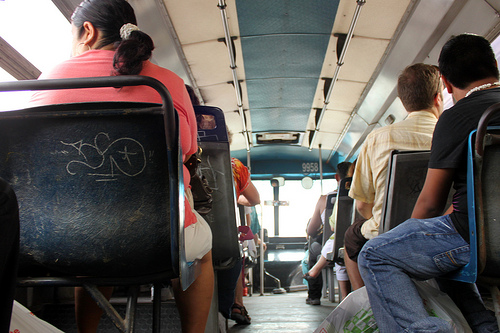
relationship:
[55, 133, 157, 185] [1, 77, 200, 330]
graffiti on seat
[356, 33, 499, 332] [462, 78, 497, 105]
bus rider wearing necklace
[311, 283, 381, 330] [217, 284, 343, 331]
shopping bag on floor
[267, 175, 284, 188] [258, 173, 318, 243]
mirror over windshield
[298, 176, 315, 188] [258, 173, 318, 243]
mirror over windshield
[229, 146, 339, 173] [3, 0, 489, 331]
trim on bus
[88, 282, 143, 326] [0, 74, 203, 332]
legs under chair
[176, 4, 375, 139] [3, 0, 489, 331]
roof in bus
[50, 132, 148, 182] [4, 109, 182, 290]
graffiti on chair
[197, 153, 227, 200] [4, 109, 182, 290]
graffitti on chair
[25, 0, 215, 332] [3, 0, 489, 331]
bus rider sitting on bus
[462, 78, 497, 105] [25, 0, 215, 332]
necklace worn by bus rider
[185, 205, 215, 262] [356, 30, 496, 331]
shorts worn by bus rider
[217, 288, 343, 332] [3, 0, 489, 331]
floor of bus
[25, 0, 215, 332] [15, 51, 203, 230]
bus rider wearing shirt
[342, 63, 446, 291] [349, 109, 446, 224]
bus rider wearing shirt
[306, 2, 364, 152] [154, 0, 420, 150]
hand rials on roof